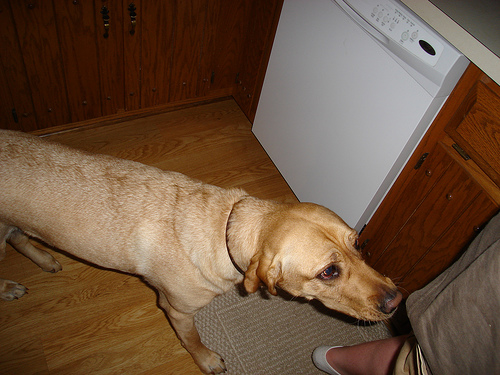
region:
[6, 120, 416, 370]
The dog is a golden color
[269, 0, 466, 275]
The dishwasher is a white color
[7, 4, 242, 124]
The cabinets are made of wood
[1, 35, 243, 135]
The cabinets are made of brown wood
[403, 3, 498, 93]
The countertop is an off-white color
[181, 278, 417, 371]
The floor mat is a tan color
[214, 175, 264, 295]
The dog is wearing a color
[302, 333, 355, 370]
The person is wearing white shoes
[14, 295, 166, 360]
The floor is made of wood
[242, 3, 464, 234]
The dishwasher is closed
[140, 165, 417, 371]
the dog is looking up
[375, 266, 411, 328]
dog's nose is brown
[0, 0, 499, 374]
the interior of a kitchen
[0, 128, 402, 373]
a dog in the kitchen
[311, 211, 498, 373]
a person standing in the kitchen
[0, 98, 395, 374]
the kitchen's hardwood floor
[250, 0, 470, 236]
a white dishwashing machine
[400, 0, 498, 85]
a beige kitchen countertop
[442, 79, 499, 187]
a kitchen cabinet drawer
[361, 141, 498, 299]
a kitchen cupboard door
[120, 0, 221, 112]
a kitchen cupboard door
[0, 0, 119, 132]
a kitchen cupboard door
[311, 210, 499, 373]
person at kitchen counter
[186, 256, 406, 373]
small tan rug for kitchen area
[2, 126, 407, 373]
dog standing behind person on rug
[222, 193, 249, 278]
brown dog collar around dog's neck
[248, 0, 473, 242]
white dishwasher under countertop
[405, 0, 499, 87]
cream-colored countertop over dishwasher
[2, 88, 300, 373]
wood flooring in home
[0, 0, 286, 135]
wooden doors with handles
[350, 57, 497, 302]
wooden cabinets underneath countertop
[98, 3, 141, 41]
metal handles on wooden doors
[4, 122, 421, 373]
Dog is brown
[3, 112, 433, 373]
Dog is begging for food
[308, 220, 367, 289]
Is looking upward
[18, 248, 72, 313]
Animal has long fingernails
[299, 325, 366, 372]
Has on white socks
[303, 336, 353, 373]
Socks are short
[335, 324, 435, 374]
Person is white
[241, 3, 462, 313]
A white stove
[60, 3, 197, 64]
the knobs on the cabinet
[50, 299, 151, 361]
Floor is made of wood